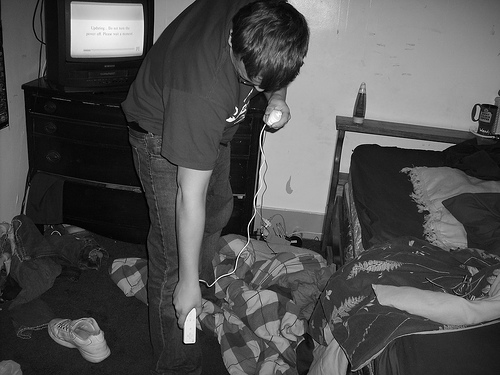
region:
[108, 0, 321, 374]
a man is bend forward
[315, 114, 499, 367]
one unmade bed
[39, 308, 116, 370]
a white tennis shoe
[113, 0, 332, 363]
man holds a game control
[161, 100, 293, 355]
game control is white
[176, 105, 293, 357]
two game controls are joined by a wire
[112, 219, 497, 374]
part of comforter in on the floor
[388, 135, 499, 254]
pillows on a bed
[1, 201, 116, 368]
pieces of cloths on the floor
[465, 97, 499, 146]
a cup on headbead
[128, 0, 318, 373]
man holding video game controllers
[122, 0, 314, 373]
man pointing down to the ground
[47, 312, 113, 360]
white shoe on the floor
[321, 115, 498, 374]
bed next to the dresser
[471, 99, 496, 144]
cup on the wooden head board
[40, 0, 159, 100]
small black television on the dresser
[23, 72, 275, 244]
black dresser behind the man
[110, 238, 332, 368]
flannel blanket on the floor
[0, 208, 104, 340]
pile of clothes on the floor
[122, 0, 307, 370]
man by the black dresser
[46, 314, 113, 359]
A white shoe on the floor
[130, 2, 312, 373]
A young man bending over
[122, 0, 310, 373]
A young man in a t-shirt and blue jeans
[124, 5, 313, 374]
A young man with short dark hair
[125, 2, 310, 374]
A young man playing with video game controllers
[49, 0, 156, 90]
A small television set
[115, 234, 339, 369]
Cloths thrown about the floor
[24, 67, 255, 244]
A small chest of drawers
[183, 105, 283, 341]
A set of Wii controllers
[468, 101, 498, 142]
A small black mug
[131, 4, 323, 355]
this is a man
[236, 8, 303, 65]
the hair is curved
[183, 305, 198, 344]
this is a remote control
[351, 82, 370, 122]
this is a bottle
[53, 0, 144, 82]
this is a tv set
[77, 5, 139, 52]
the screen is on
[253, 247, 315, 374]
this is a duvee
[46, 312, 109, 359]
this is a shoe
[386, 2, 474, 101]
the wall is white in color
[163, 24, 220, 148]
the t shirt is black in color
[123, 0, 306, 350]
a man holding a game controller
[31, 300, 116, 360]
a white shoe on the floor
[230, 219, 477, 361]
a comforter falling off the bed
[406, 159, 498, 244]
a white pillow with tassles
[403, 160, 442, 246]
tassles of the white pillow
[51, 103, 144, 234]
wooden black dresser in the corner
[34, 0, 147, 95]
black sony crt tv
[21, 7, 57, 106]
black power cords behind the tv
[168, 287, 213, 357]
white game controller in the man's hand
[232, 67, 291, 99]
glasses on the man's face